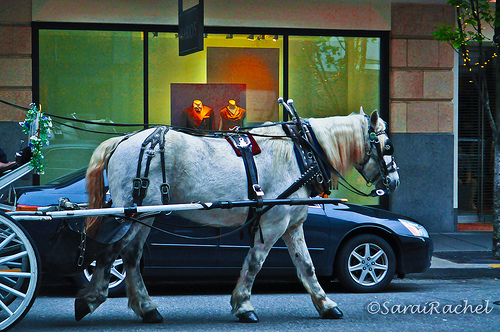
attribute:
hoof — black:
[233, 310, 258, 325]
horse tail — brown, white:
[74, 136, 119, 239]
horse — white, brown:
[69, 99, 374, 284]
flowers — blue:
[20, 99, 50, 172]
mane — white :
[256, 111, 386, 172]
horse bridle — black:
[365, 126, 396, 199]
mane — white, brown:
[311, 119, 371, 176]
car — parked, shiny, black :
[10, 158, 440, 298]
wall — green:
[44, 42, 354, 107]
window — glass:
[37, 22, 391, 219]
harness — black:
[273, 95, 338, 193]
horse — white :
[70, 97, 405, 324]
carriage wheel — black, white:
[1, 204, 53, 328]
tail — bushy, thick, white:
[70, 122, 117, 261]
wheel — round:
[334, 234, 395, 290]